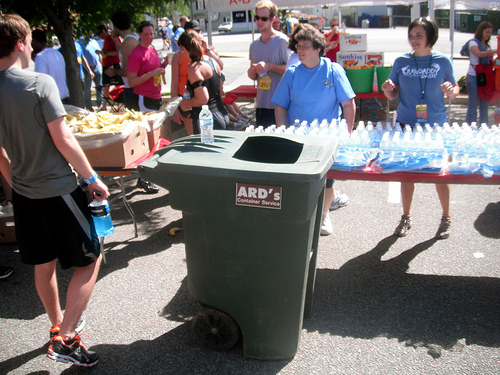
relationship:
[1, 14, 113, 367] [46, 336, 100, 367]
man with shoe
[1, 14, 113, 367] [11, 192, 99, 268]
man with shorts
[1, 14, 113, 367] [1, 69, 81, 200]
man with a shirt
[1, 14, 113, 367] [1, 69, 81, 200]
man with a t-shirt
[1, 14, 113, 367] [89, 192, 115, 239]
man with a bottle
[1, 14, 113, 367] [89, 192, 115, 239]
man with a sports drink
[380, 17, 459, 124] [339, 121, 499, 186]
woman behind a table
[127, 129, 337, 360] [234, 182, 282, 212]
bin has a company name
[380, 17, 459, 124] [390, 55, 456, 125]
woman in a shirt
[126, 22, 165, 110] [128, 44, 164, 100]
woman with a shirt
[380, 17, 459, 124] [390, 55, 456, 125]
woman with a blue shirt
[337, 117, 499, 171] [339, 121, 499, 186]
bottles on table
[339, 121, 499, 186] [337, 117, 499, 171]
table with bottles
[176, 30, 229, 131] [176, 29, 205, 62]
woman with brown hair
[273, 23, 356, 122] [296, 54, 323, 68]
woman with a sexy neck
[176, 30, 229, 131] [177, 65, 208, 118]
womans athletic arm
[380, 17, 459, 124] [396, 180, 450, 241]
womans tanned legs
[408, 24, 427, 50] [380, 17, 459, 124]
smiling face of a woman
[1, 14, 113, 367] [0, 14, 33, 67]
man sweaty head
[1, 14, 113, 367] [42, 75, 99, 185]
man fit arm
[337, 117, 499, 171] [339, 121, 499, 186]
bottled water at table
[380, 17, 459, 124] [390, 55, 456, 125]
woman wearing a shirt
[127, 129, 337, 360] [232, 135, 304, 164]
trash can has a hole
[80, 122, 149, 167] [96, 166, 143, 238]
boxes on table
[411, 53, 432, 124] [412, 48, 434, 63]
id around her neck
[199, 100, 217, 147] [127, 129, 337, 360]
water bottle on bin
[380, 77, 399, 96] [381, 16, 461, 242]
hand of woman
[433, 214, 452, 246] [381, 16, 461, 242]
foot of woman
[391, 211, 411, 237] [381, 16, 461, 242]
foot of woman